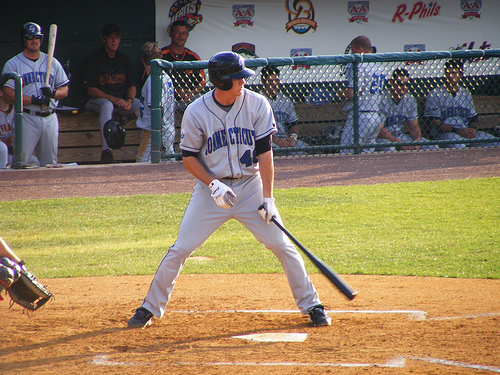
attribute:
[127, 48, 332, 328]
man — playing baseball, at bat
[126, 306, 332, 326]
shoes — black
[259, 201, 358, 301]
bat — black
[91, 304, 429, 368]
chalk box — drawn, white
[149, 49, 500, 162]
chain link fence — green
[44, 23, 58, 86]
bat — white, ready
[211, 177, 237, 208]
glove — white, bright white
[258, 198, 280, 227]
glove — white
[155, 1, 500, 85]
board — white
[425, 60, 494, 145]
player — baseball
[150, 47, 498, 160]
railing — greenish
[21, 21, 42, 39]
helmet — black, hard, baseball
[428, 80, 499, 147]
uniform — white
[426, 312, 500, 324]
line — painted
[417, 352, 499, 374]
line — painted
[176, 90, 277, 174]
shirt — white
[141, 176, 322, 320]
pants — white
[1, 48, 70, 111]
shirt — white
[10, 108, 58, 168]
pants — white